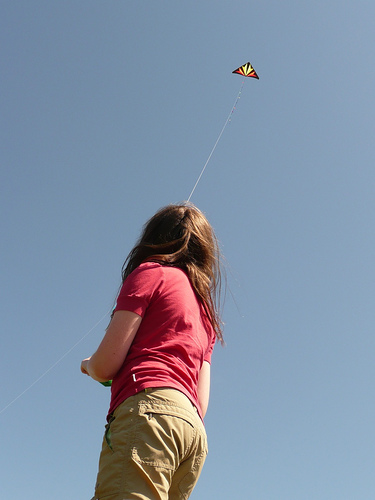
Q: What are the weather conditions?
A: It is clear.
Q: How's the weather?
A: It is clear.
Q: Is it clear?
A: Yes, it is clear.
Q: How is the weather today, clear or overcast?
A: It is clear.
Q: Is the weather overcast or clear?
A: It is clear.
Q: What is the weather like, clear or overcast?
A: It is clear.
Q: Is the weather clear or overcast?
A: It is clear.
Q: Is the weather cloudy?
A: No, it is clear.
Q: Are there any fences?
A: No, there are no fences.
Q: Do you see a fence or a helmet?
A: No, there are no fences or helmets.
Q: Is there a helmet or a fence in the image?
A: No, there are no fences or helmets.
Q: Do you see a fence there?
A: No, there are no fences.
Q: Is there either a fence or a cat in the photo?
A: No, there are no fences or cats.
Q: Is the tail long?
A: Yes, the tail is long.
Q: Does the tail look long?
A: Yes, the tail is long.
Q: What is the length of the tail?
A: The tail is long.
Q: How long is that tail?
A: The tail is long.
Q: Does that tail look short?
A: No, the tail is long.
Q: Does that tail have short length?
A: No, the tail is long.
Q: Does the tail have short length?
A: No, the tail is long.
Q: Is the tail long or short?
A: The tail is long.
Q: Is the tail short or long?
A: The tail is long.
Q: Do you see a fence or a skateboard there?
A: No, there are no fences or skateboards.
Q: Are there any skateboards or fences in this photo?
A: No, there are no fences or skateboards.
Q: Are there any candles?
A: No, there are no candles.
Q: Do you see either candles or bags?
A: No, there are no candles or bags.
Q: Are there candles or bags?
A: No, there are no candles or bags.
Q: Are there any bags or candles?
A: No, there are no candles or bags.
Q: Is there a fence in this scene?
A: No, there are no fences.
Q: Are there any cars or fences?
A: No, there are no fences or cars.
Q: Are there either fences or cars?
A: No, there are no fences or cars.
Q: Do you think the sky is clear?
A: Yes, the sky is clear.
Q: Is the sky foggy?
A: No, the sky is clear.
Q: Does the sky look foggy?
A: No, the sky is clear.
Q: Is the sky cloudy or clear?
A: The sky is clear.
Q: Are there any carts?
A: No, there are no carts.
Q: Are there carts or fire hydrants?
A: No, there are no carts or fire hydrants.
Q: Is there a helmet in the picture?
A: No, there are no helmets.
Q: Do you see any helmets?
A: No, there are no helmets.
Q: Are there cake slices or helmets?
A: No, there are no helmets or cake slices.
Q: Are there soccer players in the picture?
A: No, there are no soccer players.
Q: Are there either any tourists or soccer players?
A: No, there are no soccer players or tourists.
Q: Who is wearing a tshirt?
A: The girl is wearing a tshirt.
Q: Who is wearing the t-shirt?
A: The girl is wearing a tshirt.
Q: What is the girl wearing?
A: The girl is wearing a tshirt.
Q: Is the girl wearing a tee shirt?
A: Yes, the girl is wearing a tee shirt.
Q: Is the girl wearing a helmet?
A: No, the girl is wearing a tee shirt.